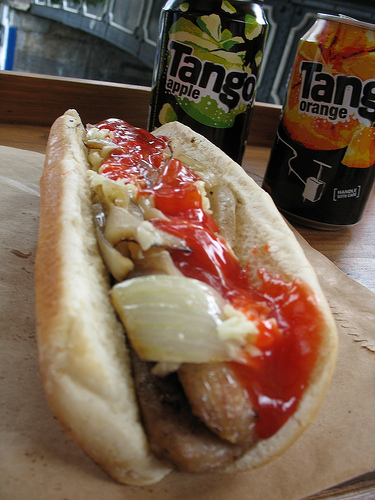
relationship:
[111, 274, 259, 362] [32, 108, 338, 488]
onion on hotdog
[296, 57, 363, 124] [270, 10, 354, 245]
tango orange on can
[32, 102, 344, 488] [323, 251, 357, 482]
hotdog on a napkin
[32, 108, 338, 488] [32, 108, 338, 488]
hotdog on a hotdog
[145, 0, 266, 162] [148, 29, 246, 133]
can has colors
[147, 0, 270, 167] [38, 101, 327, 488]
can next to hot dog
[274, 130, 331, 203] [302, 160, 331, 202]
cartoon depicting detonator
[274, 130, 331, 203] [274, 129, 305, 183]
cartoon depicting wire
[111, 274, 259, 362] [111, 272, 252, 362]
onion of onion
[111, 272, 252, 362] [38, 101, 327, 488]
onion on the hot dog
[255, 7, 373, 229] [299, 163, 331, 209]
can has detonator